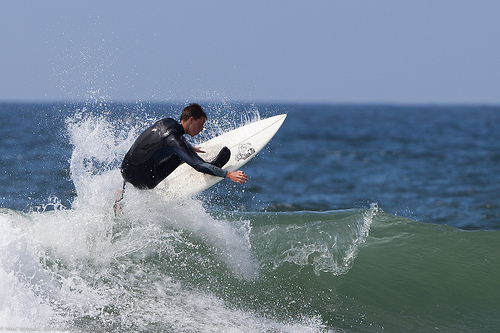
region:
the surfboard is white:
[120, 110, 321, 229]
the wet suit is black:
[112, 102, 229, 226]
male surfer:
[56, 92, 265, 218]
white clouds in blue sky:
[48, 13, 108, 59]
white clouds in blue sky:
[372, 25, 410, 66]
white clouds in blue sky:
[378, 9, 428, 91]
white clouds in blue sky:
[245, 30, 302, 95]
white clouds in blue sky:
[113, 28, 193, 75]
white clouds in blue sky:
[155, 2, 220, 67]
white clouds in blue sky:
[53, 22, 132, 83]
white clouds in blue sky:
[120, 30, 181, 107]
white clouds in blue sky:
[221, 36, 274, 69]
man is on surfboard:
[97, 88, 258, 220]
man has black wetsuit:
[111, 87, 163, 184]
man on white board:
[127, 105, 359, 195]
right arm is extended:
[131, 114, 273, 216]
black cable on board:
[88, 165, 170, 239]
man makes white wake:
[21, 123, 198, 314]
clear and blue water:
[277, 234, 488, 324]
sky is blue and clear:
[220, 30, 475, 77]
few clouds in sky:
[148, 33, 392, 108]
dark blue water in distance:
[362, 108, 466, 193]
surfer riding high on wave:
[93, 97, 292, 229]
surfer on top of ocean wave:
[87, 86, 290, 226]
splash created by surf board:
[5, 13, 291, 318]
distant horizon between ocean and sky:
[2, 87, 499, 114]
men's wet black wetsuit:
[106, 112, 249, 198]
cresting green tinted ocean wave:
[193, 197, 401, 279]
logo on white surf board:
[231, 141, 260, 168]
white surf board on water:
[72, 105, 289, 217]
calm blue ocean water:
[3, 97, 498, 233]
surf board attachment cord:
[109, 178, 130, 228]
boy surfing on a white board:
[119, 96, 251, 193]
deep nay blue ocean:
[1, 89, 496, 237]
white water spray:
[50, 35, 253, 114]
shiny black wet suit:
[116, 115, 231, 194]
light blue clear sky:
[0, 0, 499, 103]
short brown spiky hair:
[179, 100, 207, 123]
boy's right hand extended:
[216, 165, 252, 187]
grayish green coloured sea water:
[40, 212, 498, 331]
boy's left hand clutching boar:
[185, 138, 205, 157]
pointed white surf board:
[150, 105, 299, 202]